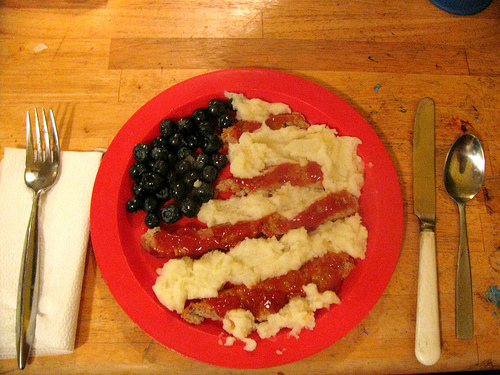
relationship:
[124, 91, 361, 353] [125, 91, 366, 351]
american flag of food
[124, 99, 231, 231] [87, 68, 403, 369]
blueberries on plate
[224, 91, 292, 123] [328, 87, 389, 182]
food on plate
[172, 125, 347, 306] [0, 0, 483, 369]
food on table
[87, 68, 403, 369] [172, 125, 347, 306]
plate of food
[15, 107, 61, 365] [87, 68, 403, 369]
fork left of plate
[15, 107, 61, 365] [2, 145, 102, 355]
fork on napkin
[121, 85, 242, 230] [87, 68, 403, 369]
blueberries on plate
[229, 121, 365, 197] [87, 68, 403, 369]
mashed potatoes on plate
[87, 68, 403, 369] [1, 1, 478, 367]
plate on surface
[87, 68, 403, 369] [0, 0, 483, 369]
plate on table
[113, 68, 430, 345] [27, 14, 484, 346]
plate on table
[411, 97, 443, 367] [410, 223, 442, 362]
knife has handle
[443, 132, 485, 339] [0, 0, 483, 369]
spoon on table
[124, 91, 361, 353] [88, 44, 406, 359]
american flag of food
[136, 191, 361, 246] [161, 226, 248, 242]
meat under ketchup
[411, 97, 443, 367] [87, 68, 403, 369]
knife beside plate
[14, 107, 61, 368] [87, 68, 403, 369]
fork beside plate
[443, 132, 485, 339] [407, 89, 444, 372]
spoon next to knife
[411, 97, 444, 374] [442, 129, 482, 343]
knife between spoon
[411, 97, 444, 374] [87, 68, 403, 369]
knife between plate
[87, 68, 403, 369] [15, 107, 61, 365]
plate right of fork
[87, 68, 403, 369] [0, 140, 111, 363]
plate right of napkin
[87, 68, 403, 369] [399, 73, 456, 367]
plate left of knife